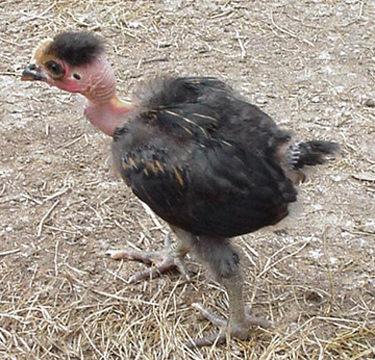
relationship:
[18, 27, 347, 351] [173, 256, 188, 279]
bird has claw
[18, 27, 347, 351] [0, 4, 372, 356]
bird standing on ground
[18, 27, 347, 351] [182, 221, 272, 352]
bird has leg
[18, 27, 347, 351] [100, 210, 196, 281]
bird has leg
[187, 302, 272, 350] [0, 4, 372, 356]
feet on ground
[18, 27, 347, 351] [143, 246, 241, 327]
bird has gray legs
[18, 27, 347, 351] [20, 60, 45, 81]
bird has beak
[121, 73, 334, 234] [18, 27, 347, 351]
feathers on bird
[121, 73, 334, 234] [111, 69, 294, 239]
feathers on body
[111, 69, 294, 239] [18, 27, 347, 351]
body on bird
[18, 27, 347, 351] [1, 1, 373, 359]
bird walking on straw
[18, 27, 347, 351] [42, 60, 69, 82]
bird has eye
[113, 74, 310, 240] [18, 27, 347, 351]
black fur of bird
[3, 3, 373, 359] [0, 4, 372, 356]
hay on ground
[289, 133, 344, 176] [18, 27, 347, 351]
tail feathers connected to bird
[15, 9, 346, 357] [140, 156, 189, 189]
bird with feather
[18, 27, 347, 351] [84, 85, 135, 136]
bird with neck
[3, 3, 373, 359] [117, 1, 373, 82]
hay on ground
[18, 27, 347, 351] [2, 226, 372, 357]
bird standing on hay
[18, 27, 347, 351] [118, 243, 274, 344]
bird has feet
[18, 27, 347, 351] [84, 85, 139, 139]
bird has neck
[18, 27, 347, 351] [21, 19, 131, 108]
bird has head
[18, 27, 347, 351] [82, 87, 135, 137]
bird has neck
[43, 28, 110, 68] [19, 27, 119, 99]
feathers on head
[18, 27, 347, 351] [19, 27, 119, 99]
bird has head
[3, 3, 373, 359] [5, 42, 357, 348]
hay littered on ground